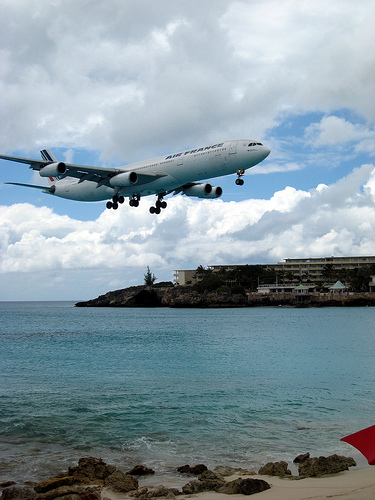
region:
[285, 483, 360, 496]
the white sand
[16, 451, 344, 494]
the rocks at the shore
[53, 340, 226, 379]
the blue ocean water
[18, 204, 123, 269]
the clouds in the sky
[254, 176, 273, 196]
part of clear blue sky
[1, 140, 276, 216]
airplane in the sky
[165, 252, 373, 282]
the big building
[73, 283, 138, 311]
the ledge of the land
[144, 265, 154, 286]
tree at the edge of land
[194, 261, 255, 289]
group of trees next to building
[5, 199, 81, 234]
a cloud in the sky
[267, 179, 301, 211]
a cloud in the sky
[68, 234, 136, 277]
a cloud in the sky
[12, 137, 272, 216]
a plane in the sky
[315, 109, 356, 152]
a cloud in the sky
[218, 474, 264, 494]
a stone in the beach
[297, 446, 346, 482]
a stone in the beach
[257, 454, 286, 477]
a stone in the beach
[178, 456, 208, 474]
a stone in the beach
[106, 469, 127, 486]
a stone in the beach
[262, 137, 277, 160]
the nose of the plane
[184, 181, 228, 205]
two engines of the plane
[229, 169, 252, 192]
the front landing gear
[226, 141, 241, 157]
door of the plane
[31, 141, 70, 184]
tail of the plane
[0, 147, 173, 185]
wing of the plane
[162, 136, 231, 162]
writing on the plane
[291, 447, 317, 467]
a rock on the shore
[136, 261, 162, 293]
a small tree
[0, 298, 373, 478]
calm blue water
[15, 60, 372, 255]
passenger plane in cloudy sky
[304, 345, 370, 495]
red umbrella on sandy beach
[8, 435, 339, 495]
sandy and rocky beach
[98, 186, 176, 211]
landing wheels of airplane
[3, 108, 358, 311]
airplane over a building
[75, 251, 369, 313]
hotel by the beach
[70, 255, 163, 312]
tree on a hill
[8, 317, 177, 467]
waves in the ocean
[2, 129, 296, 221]
blue and white airplane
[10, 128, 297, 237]
landing gear on plane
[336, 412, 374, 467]
part of red umbrella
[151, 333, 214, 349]
clear, still, blue water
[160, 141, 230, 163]
words "air france" on plane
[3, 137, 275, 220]
airplane coming in for a landing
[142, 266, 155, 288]
lone tree in distance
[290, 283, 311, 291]
light green umbrella in distance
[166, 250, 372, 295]
beachfront resort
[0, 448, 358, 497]
rocks on the beach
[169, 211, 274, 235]
puffy white clouds in sky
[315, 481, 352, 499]
sand on the beach